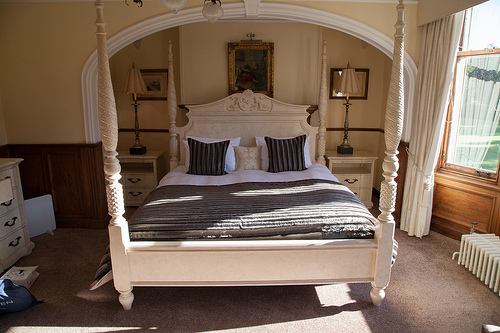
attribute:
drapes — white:
[403, 14, 458, 241]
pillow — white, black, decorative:
[256, 134, 314, 173]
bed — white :
[88, 32, 405, 303]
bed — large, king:
[92, 0, 407, 315]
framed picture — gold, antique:
[220, 32, 280, 101]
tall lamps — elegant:
[333, 66, 355, 156]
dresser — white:
[2, 143, 66, 278]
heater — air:
[452, 220, 499, 300]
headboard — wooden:
[175, 85, 322, 168]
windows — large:
[448, 40, 497, 195]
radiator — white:
[449, 220, 499, 297]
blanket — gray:
[131, 139, 374, 259]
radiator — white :
[448, 214, 489, 271]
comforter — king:
[92, 163, 392, 293]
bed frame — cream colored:
[92, 5, 410, 315]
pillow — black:
[264, 132, 306, 173]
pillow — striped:
[186, 139, 231, 171]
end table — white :
[322, 148, 379, 213]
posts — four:
[385, 1, 415, 292]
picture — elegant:
[219, 30, 289, 100]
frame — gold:
[214, 31, 294, 108]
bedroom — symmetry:
[6, 4, 484, 299]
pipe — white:
[454, 219, 483, 278]